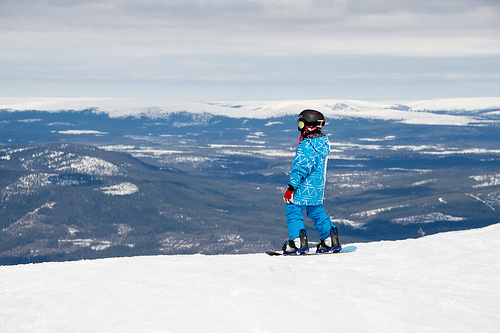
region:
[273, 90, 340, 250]
this is a boy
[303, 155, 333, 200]
this is a jacket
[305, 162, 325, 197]
the jacket is blue in color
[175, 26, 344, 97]
this is the sky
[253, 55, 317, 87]
the sky is blue in color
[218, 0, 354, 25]
these are the clouds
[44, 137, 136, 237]
this is a hill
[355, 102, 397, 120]
this is the snow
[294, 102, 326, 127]
this is a helmet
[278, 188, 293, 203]
this is a glove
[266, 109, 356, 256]
small snowboarder is contemplating the view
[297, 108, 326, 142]
black snowboarding helmet with red strap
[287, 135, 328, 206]
blue snowboarding jacket with geometric design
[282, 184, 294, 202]
left red snowboarding glove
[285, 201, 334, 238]
blue bunched up snowboarding pants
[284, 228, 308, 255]
left snowboard boot is blue and black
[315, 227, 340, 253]
right snowboard boot is blue and black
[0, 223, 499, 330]
white snow at the edge of the mountain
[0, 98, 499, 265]
snowcapped mountains look very far away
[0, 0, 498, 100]
grey overcast winter sky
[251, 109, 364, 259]
a man skiing in the heights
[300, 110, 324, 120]
this helmet is gray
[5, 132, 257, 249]
a large valley in the distance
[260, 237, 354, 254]
a blue ski baord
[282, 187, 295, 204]
a red and white glove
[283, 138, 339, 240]
dressed in blue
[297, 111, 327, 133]
the head of the skier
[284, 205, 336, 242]
the two legs of the skier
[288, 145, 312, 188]
one arm of the skier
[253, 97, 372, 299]
the skier is ready to ski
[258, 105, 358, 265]
a small snowboarder dressed in blue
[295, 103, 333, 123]
the helmet of a snowboarder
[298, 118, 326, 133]
the goggles of a snowboarder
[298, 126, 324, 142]
the scarf of a snowboarder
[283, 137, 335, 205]
the jacket of a snowboarder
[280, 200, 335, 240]
the pants of a snowboarder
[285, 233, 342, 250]
the boots of a snowboarder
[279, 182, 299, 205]
the glove of a snowboarder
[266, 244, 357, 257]
the snowboard of a snowboarder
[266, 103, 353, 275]
a snowboarder dressed in blue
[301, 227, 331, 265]
part of a board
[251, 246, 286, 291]
part of a ground